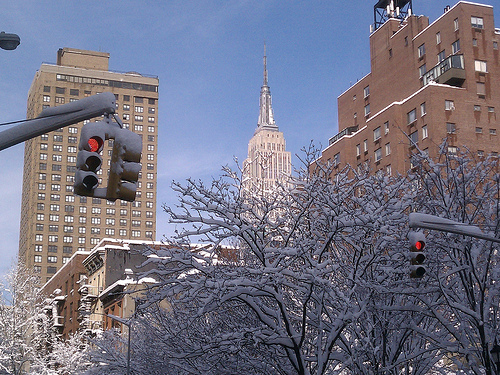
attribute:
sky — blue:
[201, 19, 291, 56]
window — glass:
[384, 139, 401, 162]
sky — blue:
[0, 1, 489, 226]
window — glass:
[407, 105, 422, 129]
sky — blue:
[306, 45, 360, 80]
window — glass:
[366, 114, 428, 166]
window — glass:
[32, 219, 49, 234]